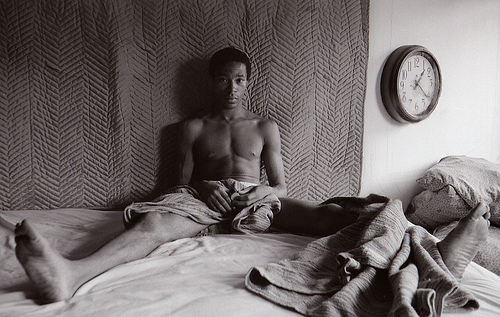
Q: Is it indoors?
A: Yes, it is indoors.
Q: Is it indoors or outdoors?
A: It is indoors.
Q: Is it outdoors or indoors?
A: It is indoors.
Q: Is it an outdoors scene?
A: No, it is indoors.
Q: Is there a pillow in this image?
A: Yes, there is a pillow.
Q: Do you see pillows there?
A: Yes, there is a pillow.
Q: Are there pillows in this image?
A: Yes, there is a pillow.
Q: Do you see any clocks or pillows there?
A: Yes, there is a pillow.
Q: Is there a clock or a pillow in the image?
A: Yes, there is a pillow.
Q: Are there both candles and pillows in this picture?
A: No, there is a pillow but no candles.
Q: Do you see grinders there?
A: No, there are no grinders.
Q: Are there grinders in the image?
A: No, there are no grinders.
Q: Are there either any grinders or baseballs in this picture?
A: No, there are no grinders or baseballs.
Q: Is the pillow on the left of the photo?
A: No, the pillow is on the right of the image.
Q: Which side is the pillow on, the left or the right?
A: The pillow is on the right of the image.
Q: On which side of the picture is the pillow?
A: The pillow is on the right of the image.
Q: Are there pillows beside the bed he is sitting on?
A: Yes, there is a pillow beside the bed.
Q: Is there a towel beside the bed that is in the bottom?
A: No, there is a pillow beside the bed.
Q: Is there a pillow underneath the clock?
A: Yes, there is a pillow underneath the clock.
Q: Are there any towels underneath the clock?
A: No, there is a pillow underneath the clock.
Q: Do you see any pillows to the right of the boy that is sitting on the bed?
A: Yes, there is a pillow to the right of the boy.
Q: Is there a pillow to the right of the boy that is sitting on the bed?
A: Yes, there is a pillow to the right of the boy.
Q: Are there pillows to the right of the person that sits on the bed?
A: Yes, there is a pillow to the right of the boy.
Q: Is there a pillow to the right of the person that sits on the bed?
A: Yes, there is a pillow to the right of the boy.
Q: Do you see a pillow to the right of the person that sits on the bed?
A: Yes, there is a pillow to the right of the boy.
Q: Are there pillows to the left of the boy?
A: No, the pillow is to the right of the boy.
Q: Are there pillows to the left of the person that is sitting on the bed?
A: No, the pillow is to the right of the boy.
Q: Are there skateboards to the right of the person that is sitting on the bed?
A: No, there is a pillow to the right of the boy.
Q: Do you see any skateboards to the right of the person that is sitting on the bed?
A: No, there is a pillow to the right of the boy.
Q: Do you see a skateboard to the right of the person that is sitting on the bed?
A: No, there is a pillow to the right of the boy.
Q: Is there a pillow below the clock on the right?
A: Yes, there is a pillow below the clock.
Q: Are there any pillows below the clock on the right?
A: Yes, there is a pillow below the clock.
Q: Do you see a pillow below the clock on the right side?
A: Yes, there is a pillow below the clock.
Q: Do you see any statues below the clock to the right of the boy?
A: No, there is a pillow below the clock.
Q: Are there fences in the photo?
A: No, there are no fences.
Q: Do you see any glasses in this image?
A: No, there are no glasses.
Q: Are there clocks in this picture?
A: Yes, there is a clock.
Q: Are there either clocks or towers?
A: Yes, there is a clock.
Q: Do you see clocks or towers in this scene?
A: Yes, there is a clock.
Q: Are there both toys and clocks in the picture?
A: No, there is a clock but no toys.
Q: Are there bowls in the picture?
A: No, there are no bowls.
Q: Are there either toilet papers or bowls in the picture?
A: No, there are no bowls or toilet papers.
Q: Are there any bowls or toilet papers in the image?
A: No, there are no bowls or toilet papers.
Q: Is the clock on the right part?
A: Yes, the clock is on the right of the image.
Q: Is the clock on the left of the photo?
A: No, the clock is on the right of the image.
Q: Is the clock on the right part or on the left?
A: The clock is on the right of the image.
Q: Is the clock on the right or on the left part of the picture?
A: The clock is on the right of the image.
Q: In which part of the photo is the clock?
A: The clock is on the right of the image.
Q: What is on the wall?
A: The clock is on the wall.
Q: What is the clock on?
A: The clock is on the wall.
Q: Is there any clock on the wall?
A: Yes, there is a clock on the wall.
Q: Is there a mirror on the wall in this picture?
A: No, there is a clock on the wall.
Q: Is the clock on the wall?
A: Yes, the clock is on the wall.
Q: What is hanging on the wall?
A: The clock is hanging on the wall.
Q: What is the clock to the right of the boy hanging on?
A: The clock is hanging on the wall.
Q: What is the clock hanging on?
A: The clock is hanging on the wall.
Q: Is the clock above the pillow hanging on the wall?
A: Yes, the clock is hanging on the wall.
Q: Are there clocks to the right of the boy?
A: Yes, there is a clock to the right of the boy.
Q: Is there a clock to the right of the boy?
A: Yes, there is a clock to the right of the boy.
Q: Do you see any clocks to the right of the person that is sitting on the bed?
A: Yes, there is a clock to the right of the boy.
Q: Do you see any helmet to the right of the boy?
A: No, there is a clock to the right of the boy.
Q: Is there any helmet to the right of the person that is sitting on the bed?
A: No, there is a clock to the right of the boy.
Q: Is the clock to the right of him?
A: Yes, the clock is to the right of the boy.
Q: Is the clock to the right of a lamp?
A: No, the clock is to the right of the boy.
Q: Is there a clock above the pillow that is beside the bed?
A: Yes, there is a clock above the pillow.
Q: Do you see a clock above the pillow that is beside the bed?
A: Yes, there is a clock above the pillow.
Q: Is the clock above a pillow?
A: Yes, the clock is above a pillow.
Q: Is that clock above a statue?
A: No, the clock is above a pillow.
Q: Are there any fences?
A: No, there are no fences.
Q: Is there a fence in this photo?
A: No, there are no fences.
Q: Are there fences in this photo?
A: No, there are no fences.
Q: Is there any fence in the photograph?
A: No, there are no fences.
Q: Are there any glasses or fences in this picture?
A: No, there are no fences or glasses.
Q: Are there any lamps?
A: No, there are no lamps.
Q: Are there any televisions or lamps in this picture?
A: No, there are no lamps or televisions.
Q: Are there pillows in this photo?
A: Yes, there is a pillow.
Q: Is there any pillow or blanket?
A: Yes, there is a pillow.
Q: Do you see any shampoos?
A: No, there are no shampoos.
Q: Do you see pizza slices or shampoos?
A: No, there are no shampoos or pizza slices.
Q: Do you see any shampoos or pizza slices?
A: No, there are no shampoos or pizza slices.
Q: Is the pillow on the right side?
A: Yes, the pillow is on the right of the image.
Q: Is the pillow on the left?
A: No, the pillow is on the right of the image.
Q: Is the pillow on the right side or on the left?
A: The pillow is on the right of the image.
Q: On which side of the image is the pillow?
A: The pillow is on the right of the image.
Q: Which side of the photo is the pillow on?
A: The pillow is on the right of the image.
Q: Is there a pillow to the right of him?
A: Yes, there is a pillow to the right of the boy.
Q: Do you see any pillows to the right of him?
A: Yes, there is a pillow to the right of the boy.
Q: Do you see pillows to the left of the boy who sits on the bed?
A: No, the pillow is to the right of the boy.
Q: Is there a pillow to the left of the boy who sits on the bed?
A: No, the pillow is to the right of the boy.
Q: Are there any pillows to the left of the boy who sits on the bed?
A: No, the pillow is to the right of the boy.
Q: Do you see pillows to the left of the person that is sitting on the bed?
A: No, the pillow is to the right of the boy.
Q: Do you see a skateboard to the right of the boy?
A: No, there is a pillow to the right of the boy.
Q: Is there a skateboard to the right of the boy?
A: No, there is a pillow to the right of the boy.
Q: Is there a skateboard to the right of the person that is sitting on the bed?
A: No, there is a pillow to the right of the boy.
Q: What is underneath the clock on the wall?
A: The pillow is underneath the clock.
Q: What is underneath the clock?
A: The pillow is underneath the clock.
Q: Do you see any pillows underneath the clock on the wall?
A: Yes, there is a pillow underneath the clock.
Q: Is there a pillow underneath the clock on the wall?
A: Yes, there is a pillow underneath the clock.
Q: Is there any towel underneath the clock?
A: No, there is a pillow underneath the clock.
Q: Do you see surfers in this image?
A: No, there are no surfers.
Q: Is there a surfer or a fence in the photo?
A: No, there are no surfers or fences.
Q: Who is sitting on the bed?
A: The boy is sitting on the bed.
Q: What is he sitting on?
A: The boy is sitting on the bed.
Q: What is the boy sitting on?
A: The boy is sitting on the bed.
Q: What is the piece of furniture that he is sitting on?
A: The piece of furniture is a bed.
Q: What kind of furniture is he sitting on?
A: The boy is sitting on the bed.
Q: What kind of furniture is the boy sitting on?
A: The boy is sitting on the bed.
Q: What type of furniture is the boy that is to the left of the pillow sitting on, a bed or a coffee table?
A: The boy is sitting on a bed.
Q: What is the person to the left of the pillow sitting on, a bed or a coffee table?
A: The boy is sitting on a bed.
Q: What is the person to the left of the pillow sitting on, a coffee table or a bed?
A: The boy is sitting on a bed.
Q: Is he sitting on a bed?
A: Yes, the boy is sitting on a bed.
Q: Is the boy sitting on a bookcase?
A: No, the boy is sitting on a bed.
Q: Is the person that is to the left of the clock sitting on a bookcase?
A: No, the boy is sitting on a bed.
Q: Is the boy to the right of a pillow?
A: No, the boy is to the left of a pillow.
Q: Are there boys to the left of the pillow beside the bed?
A: Yes, there is a boy to the left of the pillow.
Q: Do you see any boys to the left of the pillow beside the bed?
A: Yes, there is a boy to the left of the pillow.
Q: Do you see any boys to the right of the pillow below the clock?
A: No, the boy is to the left of the pillow.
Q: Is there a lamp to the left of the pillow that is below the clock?
A: No, there is a boy to the left of the pillow.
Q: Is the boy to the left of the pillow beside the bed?
A: Yes, the boy is to the left of the pillow.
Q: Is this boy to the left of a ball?
A: No, the boy is to the left of the pillow.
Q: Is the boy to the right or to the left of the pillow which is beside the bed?
A: The boy is to the left of the pillow.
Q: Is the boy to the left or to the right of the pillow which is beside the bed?
A: The boy is to the left of the pillow.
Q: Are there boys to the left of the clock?
A: Yes, there is a boy to the left of the clock.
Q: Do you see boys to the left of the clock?
A: Yes, there is a boy to the left of the clock.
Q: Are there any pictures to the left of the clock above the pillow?
A: No, there is a boy to the left of the clock.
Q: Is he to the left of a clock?
A: Yes, the boy is to the left of a clock.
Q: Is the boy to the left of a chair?
A: No, the boy is to the left of a clock.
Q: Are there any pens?
A: No, there are no pens.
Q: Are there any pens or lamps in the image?
A: No, there are no pens or lamps.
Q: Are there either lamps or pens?
A: No, there are no pens or lamps.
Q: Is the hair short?
A: Yes, the hair is short.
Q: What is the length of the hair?
A: The hair is short.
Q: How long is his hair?
A: The hair is short.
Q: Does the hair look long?
A: No, the hair is short.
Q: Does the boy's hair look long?
A: No, the hair is short.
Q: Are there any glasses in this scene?
A: No, there are no glasses.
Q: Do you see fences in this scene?
A: No, there are no fences.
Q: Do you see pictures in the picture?
A: No, there are no pictures.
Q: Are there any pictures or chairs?
A: No, there are no pictures or chairs.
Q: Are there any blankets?
A: Yes, there is a blanket.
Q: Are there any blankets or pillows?
A: Yes, there is a blanket.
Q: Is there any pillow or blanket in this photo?
A: Yes, there is a blanket.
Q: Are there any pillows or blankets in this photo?
A: Yes, there is a blanket.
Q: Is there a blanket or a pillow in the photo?
A: Yes, there is a blanket.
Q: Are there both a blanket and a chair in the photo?
A: No, there is a blanket but no chairs.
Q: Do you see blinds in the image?
A: No, there are no blinds.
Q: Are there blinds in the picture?
A: No, there are no blinds.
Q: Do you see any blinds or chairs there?
A: No, there are no blinds or chairs.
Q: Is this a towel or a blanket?
A: This is a blanket.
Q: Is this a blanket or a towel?
A: This is a blanket.